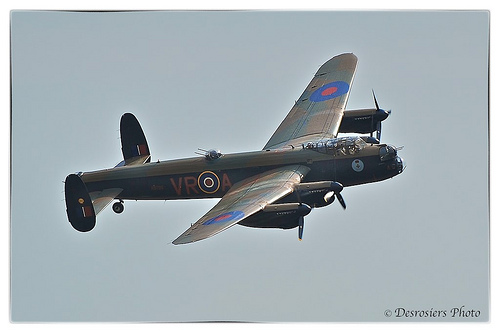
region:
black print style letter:
[395, 305, 407, 319]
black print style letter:
[403, 311, 412, 318]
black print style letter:
[409, 307, 415, 319]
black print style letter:
[412, 308, 419, 319]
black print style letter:
[419, 311, 426, 319]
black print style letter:
[424, 309, 430, 320]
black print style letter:
[428, 304, 434, 320]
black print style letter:
[431, 309, 438, 319]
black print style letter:
[436, 309, 441, 317]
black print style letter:
[450, 307, 458, 319]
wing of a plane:
[261, 43, 361, 149]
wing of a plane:
[163, 163, 312, 255]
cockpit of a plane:
[306, 127, 404, 184]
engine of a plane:
[231, 185, 316, 242]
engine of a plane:
[277, 166, 349, 211]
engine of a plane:
[332, 86, 393, 132]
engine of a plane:
[353, 118, 381, 143]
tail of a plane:
[51, 103, 165, 240]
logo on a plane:
[198, 205, 247, 230]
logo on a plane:
[307, 75, 351, 105]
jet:
[32, 37, 414, 251]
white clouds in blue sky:
[397, 250, 443, 273]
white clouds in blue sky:
[324, 273, 358, 301]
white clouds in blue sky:
[247, 246, 286, 275]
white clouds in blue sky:
[159, 280, 205, 299]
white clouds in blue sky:
[148, 50, 202, 84]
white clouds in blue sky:
[402, 30, 428, 66]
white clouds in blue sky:
[38, 232, 97, 267]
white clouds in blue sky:
[135, 28, 173, 58]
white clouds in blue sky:
[170, 4, 224, 75]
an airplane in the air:
[62, 53, 428, 317]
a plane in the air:
[89, 58, 429, 330]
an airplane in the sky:
[73, 59, 493, 319]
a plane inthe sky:
[101, 48, 454, 286]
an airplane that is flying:
[19, 41, 497, 283]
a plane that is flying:
[75, 78, 418, 292]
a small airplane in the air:
[44, 52, 473, 308]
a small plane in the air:
[59, 63, 426, 318]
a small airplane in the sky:
[64, 53, 483, 319]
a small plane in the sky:
[79, 52, 379, 262]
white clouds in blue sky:
[359, 238, 425, 266]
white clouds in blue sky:
[253, 259, 310, 306]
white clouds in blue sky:
[147, 292, 197, 325]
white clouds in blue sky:
[109, 236, 164, 283]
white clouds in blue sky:
[51, 279, 117, 315]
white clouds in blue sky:
[109, 57, 189, 91]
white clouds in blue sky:
[435, 32, 460, 73]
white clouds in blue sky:
[20, 90, 59, 118]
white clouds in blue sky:
[140, 63, 184, 83]